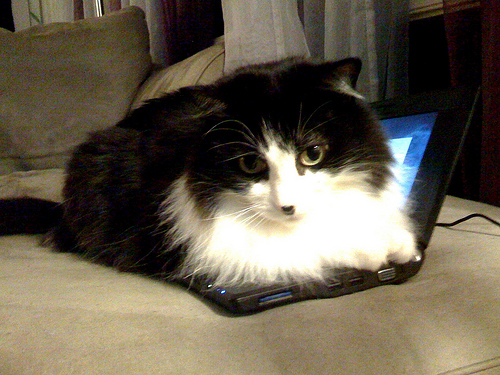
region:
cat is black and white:
[31, 61, 423, 303]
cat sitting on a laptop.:
[55, 43, 456, 305]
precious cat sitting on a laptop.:
[55, 35, 460, 322]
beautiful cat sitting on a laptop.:
[40, 31, 481, 316]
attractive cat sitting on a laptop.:
[35, 17, 465, 333]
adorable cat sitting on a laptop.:
[36, 31, 472, 331]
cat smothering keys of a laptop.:
[40, 30, 475, 335]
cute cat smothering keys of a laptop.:
[40, 40, 440, 325]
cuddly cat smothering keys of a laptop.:
[40, 25, 445, 325]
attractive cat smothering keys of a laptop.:
[52, 20, 442, 367]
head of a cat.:
[165, 48, 390, 240]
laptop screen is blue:
[327, 72, 471, 275]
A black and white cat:
[6, 60, 443, 297]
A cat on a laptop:
[63, 81, 484, 315]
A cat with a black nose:
[214, 159, 349, 253]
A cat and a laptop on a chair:
[19, 80, 407, 343]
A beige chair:
[20, 30, 224, 328]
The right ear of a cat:
[170, 62, 245, 124]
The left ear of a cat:
[312, 52, 384, 104]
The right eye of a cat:
[212, 130, 272, 197]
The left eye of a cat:
[289, 129, 355, 189]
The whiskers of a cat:
[198, 187, 275, 244]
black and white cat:
[0, 57, 426, 290]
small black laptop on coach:
[165, 81, 482, 313]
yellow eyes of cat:
[235, 143, 330, 173]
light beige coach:
[0, 3, 497, 373]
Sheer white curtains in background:
[220, 0, 410, 106]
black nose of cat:
[279, 203, 296, 213]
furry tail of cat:
[0, 195, 61, 235]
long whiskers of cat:
[205, 98, 361, 165]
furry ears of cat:
[173, 56, 373, 117]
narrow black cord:
[432, 211, 499, 232]